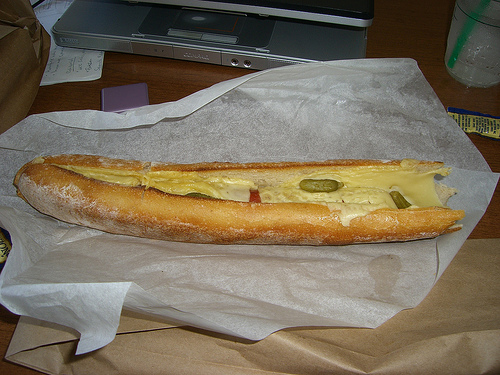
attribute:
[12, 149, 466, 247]
baguette — split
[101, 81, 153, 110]
piece — little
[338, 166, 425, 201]
cheese — yellow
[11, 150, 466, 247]
bread — long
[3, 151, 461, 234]
sandwich — baguette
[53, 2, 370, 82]
electronic device — silver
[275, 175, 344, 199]
dill pickle — green, whole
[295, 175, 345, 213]
jalapeno — sliced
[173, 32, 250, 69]
laptop — grey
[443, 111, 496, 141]
packet — yellow, blue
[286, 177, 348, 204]
jalepenos — Sliced 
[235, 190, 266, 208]
bell pepper — red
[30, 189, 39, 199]
flour — white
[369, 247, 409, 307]
stain — grease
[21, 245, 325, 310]
paper — wax